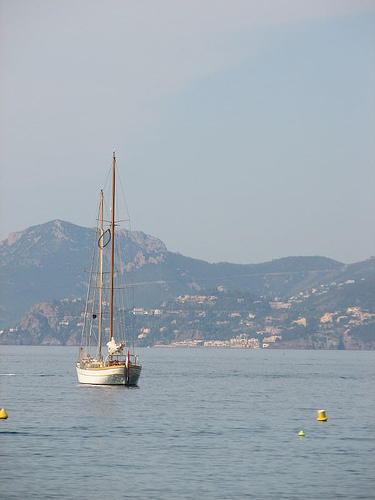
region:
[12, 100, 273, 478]
a boat sailing in front of mountains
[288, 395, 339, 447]
yellow buoys in the water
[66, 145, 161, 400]
a white sailboat with its sails down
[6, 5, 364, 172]
an overcast sky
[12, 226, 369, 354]
a town built on the side of a mountain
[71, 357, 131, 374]
a yellow stripe on the side of a boat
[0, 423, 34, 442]
a small wave in the water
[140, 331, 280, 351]
white buildings along the shore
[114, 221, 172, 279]
the rock face of a mountain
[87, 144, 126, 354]
two poles on a boat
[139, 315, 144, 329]
a tree in a distance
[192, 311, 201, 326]
a tree in a distance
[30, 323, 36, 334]
a tree in a distance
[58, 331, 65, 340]
a tree in a distance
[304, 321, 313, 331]
a tree in a distance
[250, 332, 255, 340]
a tree in a distance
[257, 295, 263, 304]
a tree in a distance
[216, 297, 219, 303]
a tree in a distance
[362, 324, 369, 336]
a tree in a distance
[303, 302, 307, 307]
a tree in a distance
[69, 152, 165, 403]
Sail boat in the water.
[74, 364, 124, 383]
Hull of the sailboat.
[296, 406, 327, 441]
Buoy and Marker in the water.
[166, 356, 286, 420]
Pale blue calm waters.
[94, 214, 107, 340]
The Mast on the sailboat.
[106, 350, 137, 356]
The boom of a sailboat.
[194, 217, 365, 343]
Hazy Mountain side.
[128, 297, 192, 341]
Houses resting at foot of mountains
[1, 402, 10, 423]
Yellow buoy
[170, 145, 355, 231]
Pale blue sky above the mountains.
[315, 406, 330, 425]
Yellow buoy in the ocean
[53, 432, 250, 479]
Calm ocean water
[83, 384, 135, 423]
Reflection of a boat on the ocean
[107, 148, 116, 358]
Long mast of a sail boat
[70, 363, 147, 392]
White sail boat in the ocean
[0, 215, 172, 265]
Mountain behind an ocean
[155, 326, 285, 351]
Buildings on an ocean front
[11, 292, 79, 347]
Rocky hill by the ocean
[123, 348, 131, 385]
Red front of a boat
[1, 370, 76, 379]
Small wave created by the moving boat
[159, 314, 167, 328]
a tree in a distance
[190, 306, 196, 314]
a tree in a distance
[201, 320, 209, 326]
a tree in a distance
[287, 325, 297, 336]
a tree in a distance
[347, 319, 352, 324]
a tree in a distance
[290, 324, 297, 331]
a tree in a distance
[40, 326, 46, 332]
a tree in a distance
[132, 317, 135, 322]
a tree in a distance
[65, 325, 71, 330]
a tree in a distance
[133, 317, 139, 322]
a tree in a distance